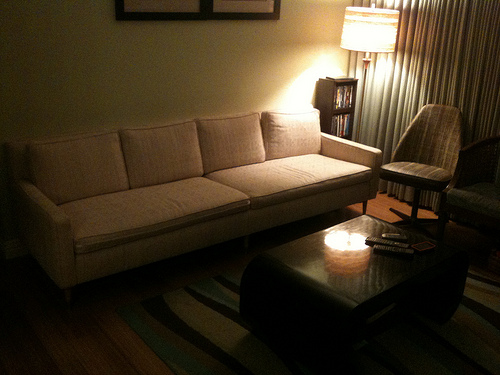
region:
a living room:
[3, 7, 495, 371]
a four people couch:
[16, 106, 361, 243]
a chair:
[393, 100, 450, 205]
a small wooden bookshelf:
[326, 72, 358, 142]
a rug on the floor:
[119, 265, 237, 374]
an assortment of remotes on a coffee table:
[356, 216, 410, 264]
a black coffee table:
[240, 215, 469, 369]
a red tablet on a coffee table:
[411, 233, 441, 264]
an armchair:
[446, 130, 498, 247]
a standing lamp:
[334, 7, 397, 154]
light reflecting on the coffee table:
[328, 225, 374, 262]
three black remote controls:
[363, 226, 417, 260]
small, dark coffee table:
[234, 212, 474, 369]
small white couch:
[14, 100, 364, 305]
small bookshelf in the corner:
[313, 73, 362, 145]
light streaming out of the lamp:
[265, 45, 432, 164]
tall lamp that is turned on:
[333, 2, 399, 149]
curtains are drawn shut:
[345, 2, 499, 207]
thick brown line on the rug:
[144, 295, 251, 374]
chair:
[380, 94, 466, 235]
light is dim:
[235, 1, 436, 172]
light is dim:
[311, 208, 379, 291]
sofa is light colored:
[11, 106, 385, 259]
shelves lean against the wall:
[311, 65, 363, 158]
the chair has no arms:
[372, 89, 474, 231]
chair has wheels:
[363, 87, 460, 235]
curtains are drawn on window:
[338, 1, 491, 221]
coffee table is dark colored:
[243, 209, 460, 360]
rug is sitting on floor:
[102, 255, 278, 374]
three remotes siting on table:
[360, 215, 432, 267]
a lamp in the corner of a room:
[336, 4, 403, 126]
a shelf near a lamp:
[323, 76, 364, 135]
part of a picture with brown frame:
[109, 2, 288, 29]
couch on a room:
[14, 96, 379, 302]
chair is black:
[374, 96, 467, 219]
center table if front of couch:
[239, 204, 476, 368]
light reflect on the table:
[305, 216, 371, 266]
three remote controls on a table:
[362, 225, 422, 271]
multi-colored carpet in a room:
[5, 216, 493, 373]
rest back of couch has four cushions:
[23, 99, 335, 202]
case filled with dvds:
[320, 71, 365, 132]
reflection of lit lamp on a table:
[315, 225, 380, 280]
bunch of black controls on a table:
[350, 226, 415, 256]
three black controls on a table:
[360, 226, 415, 256]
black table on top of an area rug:
[230, 210, 480, 355]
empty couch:
[10, 105, 385, 286]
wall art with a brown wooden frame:
[105, 0, 280, 20]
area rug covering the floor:
[1, 265, 261, 370]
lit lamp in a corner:
[334, 1, 405, 141]